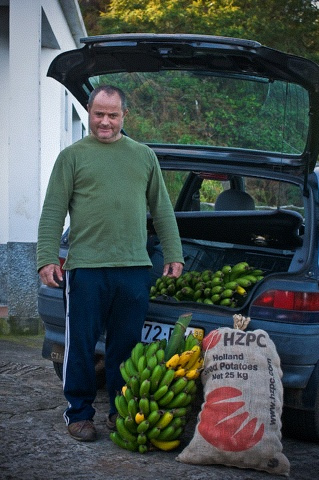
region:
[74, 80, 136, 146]
man has grey hair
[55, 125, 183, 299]
man has green shirt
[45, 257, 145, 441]
man has blue pants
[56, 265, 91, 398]
white stripe on pants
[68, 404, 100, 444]
man has brown shoes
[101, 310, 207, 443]
bunch of green bananas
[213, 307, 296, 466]
grey and burlap sack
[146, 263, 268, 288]
bunch of bananas in car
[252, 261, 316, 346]
red taillights on car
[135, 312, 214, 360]
black and white license plate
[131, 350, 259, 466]
These are bananas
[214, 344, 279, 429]
These are sweet potatoes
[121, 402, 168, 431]
The bananas are not ripe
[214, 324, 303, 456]
This is a bag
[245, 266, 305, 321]
This is a red light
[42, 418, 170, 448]
This is a pair of shoes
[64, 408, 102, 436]
The shoes are brown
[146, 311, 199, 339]
This is a license plate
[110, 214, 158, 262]
The shirt is green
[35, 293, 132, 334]
The pants are navy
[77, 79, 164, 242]
the man is standing by the car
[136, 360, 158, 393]
the bananas are green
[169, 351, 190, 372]
the banana is yellow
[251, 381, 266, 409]
the bag is tan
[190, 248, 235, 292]
the bananas are in the car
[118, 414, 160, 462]
the bananas are on the ground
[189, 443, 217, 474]
the bag is on the ground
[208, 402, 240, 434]
the design is red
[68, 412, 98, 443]
the shoe is brown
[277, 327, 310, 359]
the car is blue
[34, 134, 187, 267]
long sleeve olive shirt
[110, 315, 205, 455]
bunch of green bananas against car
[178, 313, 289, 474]
a large sack of potatoes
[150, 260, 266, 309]
bananas in trunk of car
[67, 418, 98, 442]
a brown tennis shoe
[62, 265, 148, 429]
pair of blue athletic pants with white strip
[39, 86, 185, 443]
guy standing by bunch of bananas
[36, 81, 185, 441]
guy standing behind car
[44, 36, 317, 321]
an open trunk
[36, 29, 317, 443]
a blue car with hatchback trunk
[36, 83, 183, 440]
a man standing in front of a car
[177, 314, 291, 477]
a bag of potatoes on the ground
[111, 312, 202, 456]
a bunch of bananas on a green branch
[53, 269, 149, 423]
man wearing blue Adidas pants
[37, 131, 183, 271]
man wearing a green long sleeve shirt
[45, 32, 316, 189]
an opened door to a trunk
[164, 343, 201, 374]
a bunch of yellow bananas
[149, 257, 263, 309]
bananas in the trunk of a car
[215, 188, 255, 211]
back of a driver's seat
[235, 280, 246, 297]
a yellow banana in a bunch of green bananas